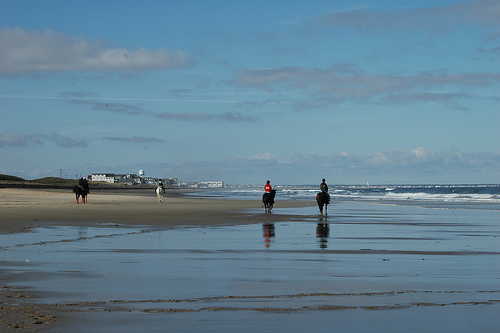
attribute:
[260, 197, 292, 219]
horse — brown, browny, walking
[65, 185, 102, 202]
horse — brown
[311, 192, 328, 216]
horse — brown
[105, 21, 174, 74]
sky — cloudy, cloudyy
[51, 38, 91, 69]
cloud — gray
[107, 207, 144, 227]
sand — brown, wet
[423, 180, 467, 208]
water — blue